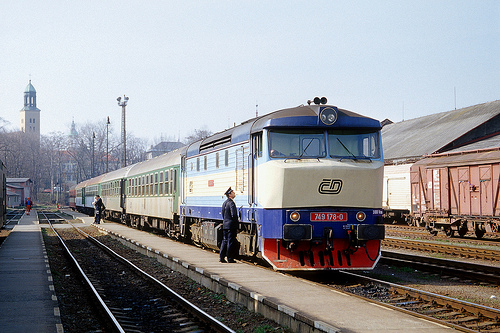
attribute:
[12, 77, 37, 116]
dome — green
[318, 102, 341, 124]
light — large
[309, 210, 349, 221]
sign — red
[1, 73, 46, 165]
building — tall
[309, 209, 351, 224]
tag — red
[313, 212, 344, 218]
text — white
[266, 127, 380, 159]
windows — Clean 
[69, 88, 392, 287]
train — blue, white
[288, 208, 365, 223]
headlights — on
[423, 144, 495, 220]
train car — dark, red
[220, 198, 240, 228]
jacket — blue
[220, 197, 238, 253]
clothes — black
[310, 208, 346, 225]
lettering — white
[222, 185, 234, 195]
cap — black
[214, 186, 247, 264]
worker — talking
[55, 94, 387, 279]
train — red, blue, white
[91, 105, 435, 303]
train — empty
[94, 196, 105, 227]
employee — railroad